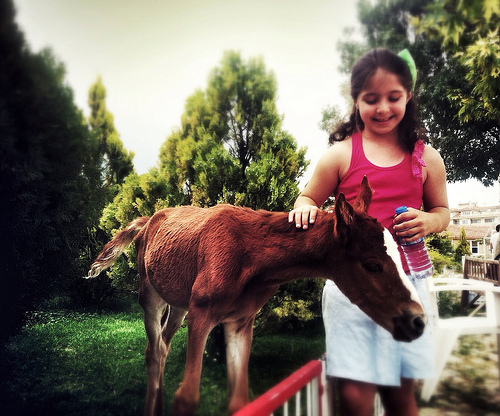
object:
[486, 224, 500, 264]
person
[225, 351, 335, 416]
fence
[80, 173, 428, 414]
horse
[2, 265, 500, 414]
yard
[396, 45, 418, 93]
bow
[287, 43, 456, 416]
girl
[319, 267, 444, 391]
skirt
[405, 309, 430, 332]
nose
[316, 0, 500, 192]
green tree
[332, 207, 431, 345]
horse's face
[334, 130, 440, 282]
tank top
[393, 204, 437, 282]
water bottle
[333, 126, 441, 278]
top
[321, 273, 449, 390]
shorts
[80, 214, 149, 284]
tail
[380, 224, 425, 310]
patch